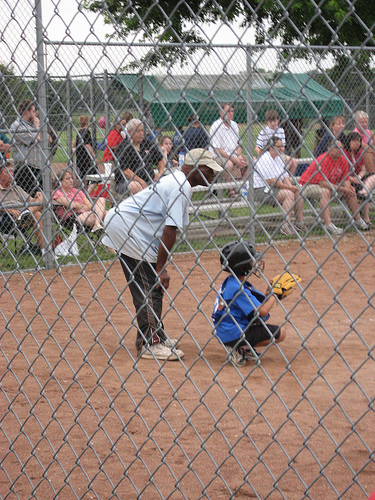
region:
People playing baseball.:
[16, 55, 368, 481]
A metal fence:
[43, 119, 352, 468]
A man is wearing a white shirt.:
[106, 154, 198, 263]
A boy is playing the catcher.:
[207, 227, 298, 362]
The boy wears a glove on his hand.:
[266, 269, 291, 291]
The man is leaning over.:
[94, 128, 212, 379]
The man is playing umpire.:
[83, 97, 222, 407]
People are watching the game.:
[37, 83, 312, 169]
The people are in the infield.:
[64, 119, 322, 368]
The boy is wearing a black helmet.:
[218, 230, 261, 275]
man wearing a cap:
[92, 130, 222, 382]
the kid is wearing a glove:
[209, 228, 301, 397]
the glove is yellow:
[266, 266, 301, 320]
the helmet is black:
[194, 223, 279, 298]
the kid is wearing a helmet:
[219, 224, 303, 376]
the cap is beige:
[172, 142, 222, 188]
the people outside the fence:
[19, 101, 373, 280]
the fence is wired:
[22, 303, 218, 485]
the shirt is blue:
[209, 263, 277, 347]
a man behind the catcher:
[93, 143, 285, 406]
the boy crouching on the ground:
[211, 240, 301, 366]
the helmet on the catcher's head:
[220, 241, 261, 266]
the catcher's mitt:
[269, 271, 302, 297]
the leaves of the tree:
[76, 0, 373, 80]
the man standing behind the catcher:
[102, 148, 224, 359]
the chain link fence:
[1, 1, 372, 498]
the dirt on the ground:
[4, 253, 373, 498]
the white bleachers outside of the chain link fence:
[83, 150, 372, 233]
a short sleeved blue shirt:
[213, 275, 268, 339]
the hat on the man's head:
[185, 146, 223, 172]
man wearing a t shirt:
[105, 127, 226, 376]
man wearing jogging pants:
[120, 125, 220, 358]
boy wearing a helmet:
[199, 229, 309, 364]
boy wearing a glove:
[198, 233, 297, 417]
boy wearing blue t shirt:
[208, 232, 287, 367]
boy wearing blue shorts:
[196, 230, 296, 373]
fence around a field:
[127, 366, 289, 473]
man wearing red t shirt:
[300, 132, 360, 231]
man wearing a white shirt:
[212, 97, 251, 190]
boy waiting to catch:
[212, 238, 302, 367]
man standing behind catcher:
[99, 144, 226, 363]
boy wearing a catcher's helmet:
[212, 240, 303, 364]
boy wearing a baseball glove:
[212, 240, 304, 366]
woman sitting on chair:
[50, 170, 121, 256]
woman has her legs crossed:
[51, 168, 129, 255]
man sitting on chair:
[1, 158, 64, 263]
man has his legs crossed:
[0, 159, 68, 266]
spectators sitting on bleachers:
[81, 101, 374, 230]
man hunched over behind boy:
[99, 142, 226, 363]